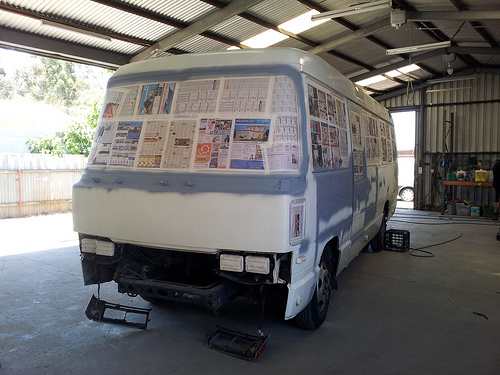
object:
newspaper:
[88, 70, 402, 175]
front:
[76, 230, 301, 322]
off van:
[74, 230, 315, 364]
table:
[435, 175, 500, 217]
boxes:
[469, 204, 481, 218]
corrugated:
[419, 71, 500, 213]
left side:
[202, 321, 271, 363]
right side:
[81, 293, 155, 335]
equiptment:
[438, 109, 459, 215]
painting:
[440, 118, 497, 187]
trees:
[22, 99, 105, 158]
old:
[67, 44, 400, 331]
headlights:
[244, 254, 271, 275]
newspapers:
[215, 76, 272, 116]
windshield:
[88, 71, 305, 182]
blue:
[72, 167, 309, 200]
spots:
[298, 237, 311, 255]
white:
[318, 205, 353, 237]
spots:
[378, 181, 383, 191]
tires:
[288, 240, 336, 332]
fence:
[0, 152, 87, 221]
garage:
[0, 0, 500, 375]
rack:
[441, 154, 494, 187]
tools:
[473, 168, 488, 181]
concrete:
[0, 208, 500, 375]